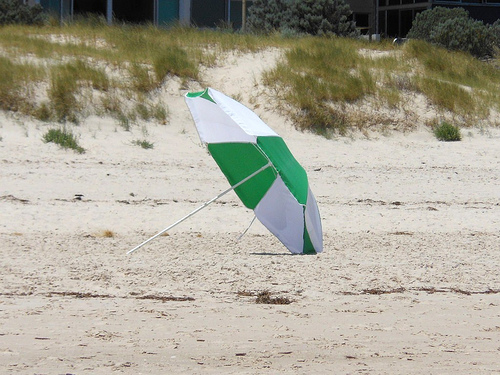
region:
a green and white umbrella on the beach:
[98, 73, 371, 319]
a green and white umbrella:
[106, 74, 355, 274]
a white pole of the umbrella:
[118, 163, 273, 258]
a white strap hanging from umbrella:
[235, 215, 254, 243]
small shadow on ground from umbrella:
[248, 247, 295, 259]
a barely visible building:
[34, 2, 483, 53]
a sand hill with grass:
[3, 18, 491, 185]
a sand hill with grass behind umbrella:
[8, 16, 493, 146]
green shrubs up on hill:
[398, 9, 494, 89]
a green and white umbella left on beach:
[104, 77, 356, 264]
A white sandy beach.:
[3, 148, 493, 373]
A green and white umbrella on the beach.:
[119, 85, 329, 267]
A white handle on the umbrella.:
[122, 153, 272, 258]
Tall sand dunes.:
[3, 22, 498, 151]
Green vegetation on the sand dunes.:
[1, 23, 494, 151]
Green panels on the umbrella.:
[202, 141, 311, 203]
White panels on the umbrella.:
[174, 91, 280, 143]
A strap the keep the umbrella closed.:
[237, 208, 262, 243]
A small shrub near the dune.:
[433, 120, 460, 145]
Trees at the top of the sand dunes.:
[405, 2, 498, 56]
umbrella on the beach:
[94, 82, 321, 282]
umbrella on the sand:
[98, 82, 339, 270]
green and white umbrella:
[104, 78, 341, 268]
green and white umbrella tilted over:
[110, 76, 324, 277]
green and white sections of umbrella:
[181, 82, 326, 264]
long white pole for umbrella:
[124, 165, 261, 260]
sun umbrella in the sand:
[114, 72, 316, 297]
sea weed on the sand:
[60, 273, 300, 324]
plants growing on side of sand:
[285, 39, 469, 143]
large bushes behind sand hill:
[390, 0, 480, 61]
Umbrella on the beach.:
[101, 77, 386, 298]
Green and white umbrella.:
[175, 75, 386, 354]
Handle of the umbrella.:
[93, 151, 230, 264]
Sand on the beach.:
[26, 225, 323, 342]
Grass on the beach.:
[31, 110, 119, 170]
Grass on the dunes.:
[246, 32, 486, 166]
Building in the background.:
[37, 1, 359, 39]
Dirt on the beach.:
[208, 278, 315, 321]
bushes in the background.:
[406, 6, 498, 66]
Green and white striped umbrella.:
[168, 75, 365, 286]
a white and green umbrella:
[121, 75, 318, 290]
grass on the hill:
[7, 23, 499, 148]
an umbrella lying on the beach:
[95, 69, 345, 305]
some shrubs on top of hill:
[233, 3, 498, 72]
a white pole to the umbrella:
[120, 157, 284, 268]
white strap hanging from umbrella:
[233, 214, 256, 261]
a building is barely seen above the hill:
[51, 3, 498, 60]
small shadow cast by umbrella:
[248, 244, 295, 261]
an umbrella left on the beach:
[96, 70, 359, 290]